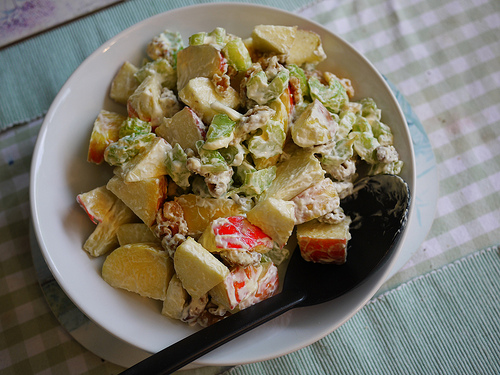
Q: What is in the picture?
A: A salad.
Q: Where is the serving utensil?
A: Inside the bowl.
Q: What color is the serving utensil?
A: Black.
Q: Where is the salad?
A: The table.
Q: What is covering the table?
A: Tablecloth.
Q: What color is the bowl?
A: White.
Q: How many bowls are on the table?
A: One.